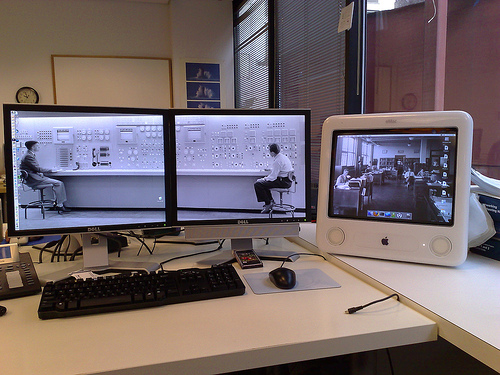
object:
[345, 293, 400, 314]
cord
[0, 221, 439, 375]
desk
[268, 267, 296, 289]
mouse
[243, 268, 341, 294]
pad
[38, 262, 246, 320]
keyboard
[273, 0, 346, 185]
blinds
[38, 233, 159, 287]
base on computer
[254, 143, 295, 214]
man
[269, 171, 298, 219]
stool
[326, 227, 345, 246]
knob on screen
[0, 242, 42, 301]
telephone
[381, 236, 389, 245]
logo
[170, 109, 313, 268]
computers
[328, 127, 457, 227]
apple monitor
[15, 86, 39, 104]
clock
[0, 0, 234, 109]
wall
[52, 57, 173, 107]
board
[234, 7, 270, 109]
blinds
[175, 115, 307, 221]
monitor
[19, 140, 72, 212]
man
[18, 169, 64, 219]
stool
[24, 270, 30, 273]
buttons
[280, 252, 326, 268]
cord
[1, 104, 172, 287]
computer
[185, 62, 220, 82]
poster